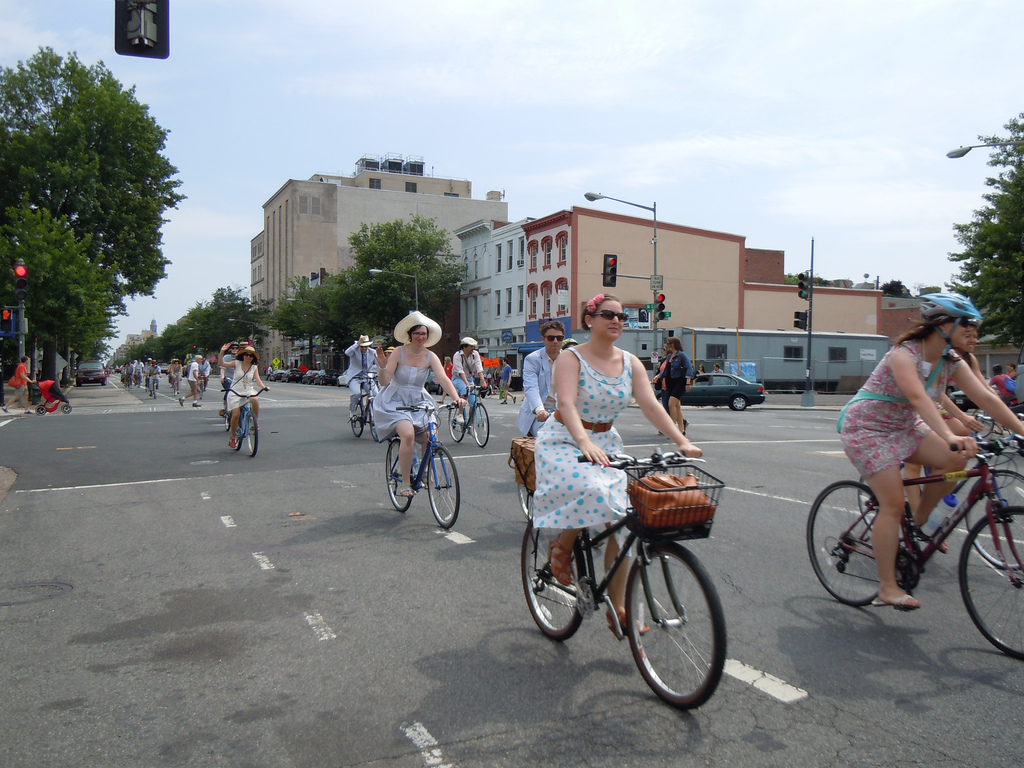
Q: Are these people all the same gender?
A: No, they are both male and female.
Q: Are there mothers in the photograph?
A: No, there are no mothers.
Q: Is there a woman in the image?
A: Yes, there is a woman.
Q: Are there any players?
A: No, there are no players.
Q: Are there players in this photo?
A: No, there are no players.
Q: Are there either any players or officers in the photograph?
A: No, there are no players or officers.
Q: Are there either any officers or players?
A: No, there are no players or officers.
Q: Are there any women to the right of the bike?
A: Yes, there is a woman to the right of the bike.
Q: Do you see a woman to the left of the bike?
A: No, the woman is to the right of the bike.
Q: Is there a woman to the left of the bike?
A: No, the woman is to the right of the bike.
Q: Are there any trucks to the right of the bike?
A: No, there is a woman to the right of the bike.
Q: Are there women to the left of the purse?
A: No, the woman is to the right of the purse.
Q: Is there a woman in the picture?
A: Yes, there is a woman.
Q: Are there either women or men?
A: Yes, there is a woman.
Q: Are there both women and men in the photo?
A: Yes, there are both a woman and a man.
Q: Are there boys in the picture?
A: No, there are no boys.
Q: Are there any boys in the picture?
A: No, there are no boys.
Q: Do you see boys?
A: No, there are no boys.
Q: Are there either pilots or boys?
A: No, there are no boys or pilots.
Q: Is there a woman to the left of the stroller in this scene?
A: Yes, there is a woman to the left of the stroller.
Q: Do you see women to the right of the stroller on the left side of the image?
A: No, the woman is to the left of the stroller.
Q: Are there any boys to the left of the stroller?
A: No, there is a woman to the left of the stroller.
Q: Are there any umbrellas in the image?
A: No, there are no umbrellas.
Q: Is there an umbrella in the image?
A: No, there are no umbrellas.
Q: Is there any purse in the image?
A: Yes, there is a purse.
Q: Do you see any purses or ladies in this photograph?
A: Yes, there is a purse.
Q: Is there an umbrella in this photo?
A: No, there are no umbrellas.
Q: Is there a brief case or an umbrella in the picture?
A: No, there are no umbrellas or briefcases.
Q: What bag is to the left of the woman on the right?
A: The bag is a purse.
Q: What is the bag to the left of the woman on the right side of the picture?
A: The bag is a purse.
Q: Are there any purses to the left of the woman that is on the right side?
A: Yes, there is a purse to the left of the woman.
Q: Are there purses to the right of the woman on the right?
A: No, the purse is to the left of the woman.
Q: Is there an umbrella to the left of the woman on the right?
A: No, there is a purse to the left of the woman.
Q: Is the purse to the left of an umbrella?
A: No, the purse is to the left of a woman.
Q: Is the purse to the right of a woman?
A: No, the purse is to the left of a woman.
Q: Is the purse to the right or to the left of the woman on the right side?
A: The purse is to the left of the woman.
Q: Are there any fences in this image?
A: No, there are no fences.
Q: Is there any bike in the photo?
A: Yes, there is a bike.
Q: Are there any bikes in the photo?
A: Yes, there is a bike.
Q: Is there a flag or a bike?
A: Yes, there is a bike.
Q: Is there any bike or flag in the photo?
A: Yes, there is a bike.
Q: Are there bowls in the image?
A: No, there are no bowls.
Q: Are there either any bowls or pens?
A: No, there are no bowls or pens.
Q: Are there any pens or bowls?
A: No, there are no bowls or pens.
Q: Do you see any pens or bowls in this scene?
A: No, there are no bowls or pens.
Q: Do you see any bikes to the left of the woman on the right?
A: Yes, there is a bike to the left of the woman.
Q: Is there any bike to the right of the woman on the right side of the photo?
A: No, the bike is to the left of the woman.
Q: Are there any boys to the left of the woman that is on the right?
A: No, there is a bike to the left of the woman.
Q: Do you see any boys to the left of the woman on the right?
A: No, there is a bike to the left of the woman.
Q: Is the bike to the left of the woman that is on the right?
A: Yes, the bike is to the left of the woman.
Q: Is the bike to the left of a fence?
A: No, the bike is to the left of the woman.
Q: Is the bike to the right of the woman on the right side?
A: No, the bike is to the left of the woman.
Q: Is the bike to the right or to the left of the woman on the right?
A: The bike is to the left of the woman.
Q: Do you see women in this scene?
A: Yes, there is a woman.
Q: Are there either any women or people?
A: Yes, there is a woman.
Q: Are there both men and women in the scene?
A: Yes, there are both a woman and a man.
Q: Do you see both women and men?
A: Yes, there are both a woman and a man.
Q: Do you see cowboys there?
A: No, there are no cowboys.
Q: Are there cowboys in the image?
A: No, there are no cowboys.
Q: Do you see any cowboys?
A: No, there are no cowboys.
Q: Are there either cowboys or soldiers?
A: No, there are no cowboys or soldiers.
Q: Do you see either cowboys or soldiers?
A: No, there are no cowboys or soldiers.